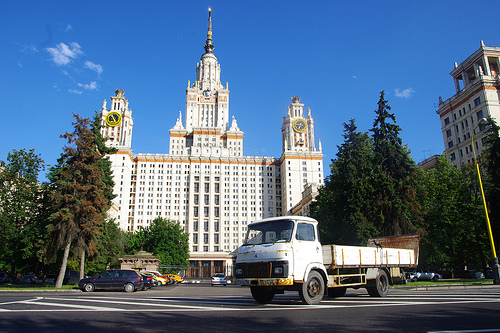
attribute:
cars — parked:
[74, 262, 189, 294]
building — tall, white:
[435, 40, 499, 175]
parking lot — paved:
[80, 246, 250, 330]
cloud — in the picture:
[20, 26, 107, 102]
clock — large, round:
[292, 116, 307, 133]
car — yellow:
[148, 267, 184, 287]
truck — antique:
[200, 199, 469, 296]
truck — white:
[233, 210, 417, 298]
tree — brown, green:
[20, 94, 135, 257]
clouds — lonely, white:
[39, 30, 97, 70]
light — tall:
[464, 114, 499, 285]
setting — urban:
[66, 5, 350, 300]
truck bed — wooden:
[318, 236, 417, 282]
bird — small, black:
[369, 229, 384, 254]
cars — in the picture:
[79, 260, 217, 320]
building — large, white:
[52, 22, 384, 295]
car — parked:
[82, 248, 157, 313]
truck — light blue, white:
[229, 215, 421, 305]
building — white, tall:
[93, 2, 325, 281]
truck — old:
[224, 208, 424, 305]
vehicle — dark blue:
[242, 190, 417, 308]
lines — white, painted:
[5, 287, 495, 308]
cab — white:
[231, 216, 325, 292]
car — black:
[81, 269, 141, 290]